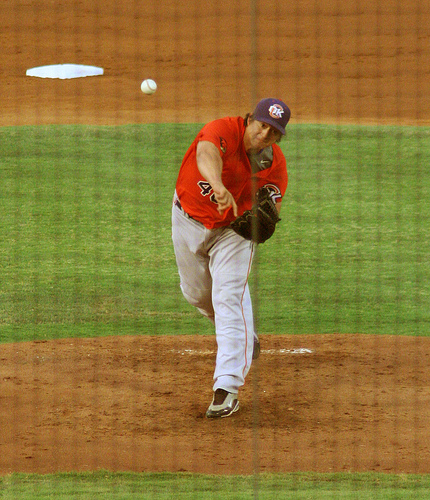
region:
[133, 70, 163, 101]
White baseball with red trim in the air.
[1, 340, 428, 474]
Dirt where the player is standing.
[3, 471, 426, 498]
Grass in front of the player.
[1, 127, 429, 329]
Grass behind the player.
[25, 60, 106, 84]
Base behind the player.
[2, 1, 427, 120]
Dirt area where the base is.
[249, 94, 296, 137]
Baseball cap on the player's head.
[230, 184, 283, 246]
Baseball glove on the player's hand.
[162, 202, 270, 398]
Uniform pants the player is wearing.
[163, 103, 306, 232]
Red uniform shirt the player is wearing.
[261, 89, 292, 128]
Dark blue baseball cap on the player's head.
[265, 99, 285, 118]
Design on the baseball cap on the player's head.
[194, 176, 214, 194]
Number 4 on the player's uniform.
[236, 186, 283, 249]
Black baseball glove on the player's hand.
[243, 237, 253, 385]
Red stripe on the player's uniform pants.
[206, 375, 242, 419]
Right gray and black sneaker on the player's foot.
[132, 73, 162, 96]
White baseball in the air.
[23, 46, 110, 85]
White base behind the player.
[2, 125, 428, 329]
Grass behind the baseball player.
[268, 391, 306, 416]
white spot on the dirt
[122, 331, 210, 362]
white line covered with dirt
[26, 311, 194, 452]
brown dirt at home mound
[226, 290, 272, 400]
orange line down side of pants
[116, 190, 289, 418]
man wearing gray pants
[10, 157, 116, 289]
well manicured green grass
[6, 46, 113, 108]
large white pad on dirt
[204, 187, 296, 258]
black gloves on man's hand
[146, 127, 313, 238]
red shirt with black numbers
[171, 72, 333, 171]
purple hat wit white and orange symbol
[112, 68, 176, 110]
a white baseball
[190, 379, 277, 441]
athletic sneakers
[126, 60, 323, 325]
a baseball player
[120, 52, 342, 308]
a baseball player throwing a baseball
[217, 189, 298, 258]
a baseball glove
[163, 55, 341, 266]
a baseball player wearing a hat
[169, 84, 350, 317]
a baseball player holding a baseball glove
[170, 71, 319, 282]
a baseball player wearing a orange shirt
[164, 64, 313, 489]
a baseball player wearing grey pants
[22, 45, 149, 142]
a white baseball base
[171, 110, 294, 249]
red short sleeve baseball jersey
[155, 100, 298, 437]
baseball pitcher throwing ball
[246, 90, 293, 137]
dark blue cap on player's head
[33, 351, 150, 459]
borwn dirt on pitcher's mound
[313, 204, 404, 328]
green grass on baseball field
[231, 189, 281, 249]
black leather catcher's mitt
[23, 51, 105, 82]
white plate on field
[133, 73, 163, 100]
baseball flying through the air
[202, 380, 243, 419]
baseball cleat on pitcher's foot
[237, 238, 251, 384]
red pinstripe on white pants